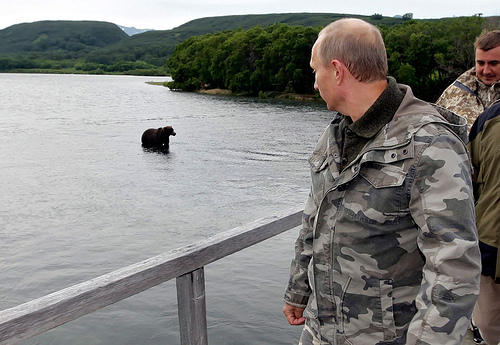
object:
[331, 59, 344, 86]
ear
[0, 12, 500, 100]
green trees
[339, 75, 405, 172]
shirt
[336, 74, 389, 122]
neck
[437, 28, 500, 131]
man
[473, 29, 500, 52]
brown hair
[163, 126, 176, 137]
head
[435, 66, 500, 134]
coat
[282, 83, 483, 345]
coat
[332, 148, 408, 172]
buttons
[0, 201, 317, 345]
hand rails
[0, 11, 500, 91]
hills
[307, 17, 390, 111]
head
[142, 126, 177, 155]
bear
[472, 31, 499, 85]
head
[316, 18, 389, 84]
gray hair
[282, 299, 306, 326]
hand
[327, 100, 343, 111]
chin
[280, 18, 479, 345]
man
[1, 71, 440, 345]
water